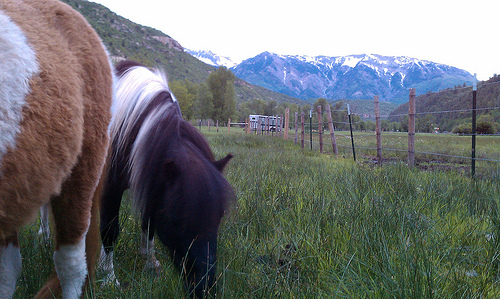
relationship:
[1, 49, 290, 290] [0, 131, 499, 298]
horses are grass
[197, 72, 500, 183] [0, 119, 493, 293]
fence in field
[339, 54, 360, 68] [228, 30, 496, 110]
snow on mountain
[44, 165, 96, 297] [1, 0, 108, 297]
leg on horse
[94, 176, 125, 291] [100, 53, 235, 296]
leg on horse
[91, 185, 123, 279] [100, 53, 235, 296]
leg on horse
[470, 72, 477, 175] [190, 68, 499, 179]
post on fence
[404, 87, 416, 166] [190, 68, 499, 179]
post on fence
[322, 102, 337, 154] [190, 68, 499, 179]
post on fence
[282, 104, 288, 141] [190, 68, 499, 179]
post on fence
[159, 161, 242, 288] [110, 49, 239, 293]
head of a horse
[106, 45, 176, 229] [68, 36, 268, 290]
mane of a horse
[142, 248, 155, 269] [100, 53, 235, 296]
hoof of a horse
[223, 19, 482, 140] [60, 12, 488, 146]
mountains in distance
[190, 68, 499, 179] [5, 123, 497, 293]
fence along grass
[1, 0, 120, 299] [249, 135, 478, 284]
horses grazing in grass